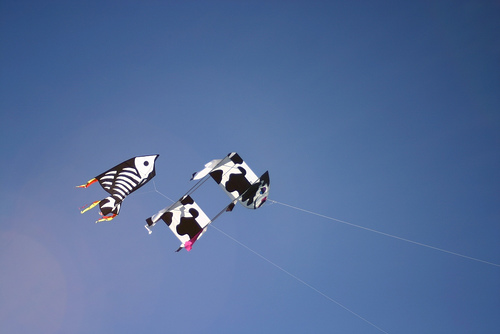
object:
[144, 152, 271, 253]
kite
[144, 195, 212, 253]
tail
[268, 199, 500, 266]
line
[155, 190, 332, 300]
line